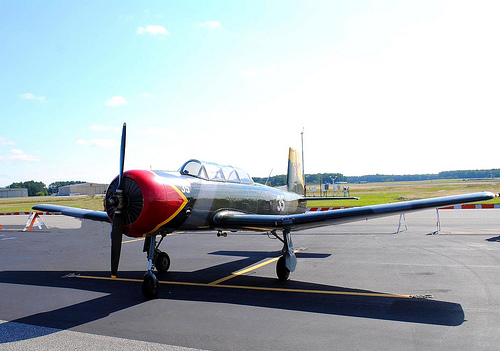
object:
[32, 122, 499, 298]
airplane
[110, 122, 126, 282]
propeller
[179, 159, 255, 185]
hatch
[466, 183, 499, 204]
grass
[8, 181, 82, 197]
tree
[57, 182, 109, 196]
building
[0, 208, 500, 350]
asphalt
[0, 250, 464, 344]
shadow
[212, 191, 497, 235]
wing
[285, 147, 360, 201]
tail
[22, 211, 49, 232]
barrier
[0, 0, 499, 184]
sky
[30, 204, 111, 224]
wing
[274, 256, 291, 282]
wheel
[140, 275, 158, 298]
wheel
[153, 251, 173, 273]
wheel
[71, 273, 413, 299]
line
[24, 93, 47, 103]
cloud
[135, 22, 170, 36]
cloud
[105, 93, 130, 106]
cloud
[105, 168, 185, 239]
nose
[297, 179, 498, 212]
field